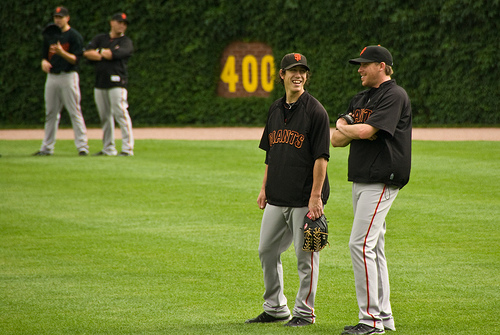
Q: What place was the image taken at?
A: It was taken at the field.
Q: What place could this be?
A: It is a field.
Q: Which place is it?
A: It is a field.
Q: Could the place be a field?
A: Yes, it is a field.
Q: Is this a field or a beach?
A: It is a field.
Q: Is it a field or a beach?
A: It is a field.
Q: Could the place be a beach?
A: No, it is a field.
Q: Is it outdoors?
A: Yes, it is outdoors.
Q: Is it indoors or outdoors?
A: It is outdoors.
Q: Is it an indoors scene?
A: No, it is outdoors.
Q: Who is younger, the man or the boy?
A: The boy is younger than the man.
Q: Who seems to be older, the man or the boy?
A: The man is older than the boy.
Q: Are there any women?
A: No, there are no women.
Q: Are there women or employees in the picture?
A: No, there are no women or employees.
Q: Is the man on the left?
A: Yes, the man is on the left of the image.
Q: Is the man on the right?
A: No, the man is on the left of the image.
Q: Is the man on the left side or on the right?
A: The man is on the left of the image.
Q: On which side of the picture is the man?
A: The man is on the left of the image.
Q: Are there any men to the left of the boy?
A: Yes, there is a man to the left of the boy.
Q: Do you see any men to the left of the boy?
A: Yes, there is a man to the left of the boy.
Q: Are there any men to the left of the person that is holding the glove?
A: Yes, there is a man to the left of the boy.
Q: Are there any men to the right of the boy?
A: No, the man is to the left of the boy.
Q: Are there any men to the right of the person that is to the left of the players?
A: No, the man is to the left of the boy.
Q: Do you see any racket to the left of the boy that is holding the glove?
A: No, there is a man to the left of the boy.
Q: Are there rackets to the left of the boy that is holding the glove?
A: No, there is a man to the left of the boy.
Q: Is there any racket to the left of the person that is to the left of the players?
A: No, there is a man to the left of the boy.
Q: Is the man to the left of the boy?
A: Yes, the man is to the left of the boy.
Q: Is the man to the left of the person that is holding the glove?
A: Yes, the man is to the left of the boy.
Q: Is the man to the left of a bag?
A: No, the man is to the left of the boy.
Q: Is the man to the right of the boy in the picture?
A: No, the man is to the left of the boy.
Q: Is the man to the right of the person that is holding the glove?
A: No, the man is to the left of the boy.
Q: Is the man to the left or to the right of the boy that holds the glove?
A: The man is to the left of the boy.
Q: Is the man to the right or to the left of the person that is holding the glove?
A: The man is to the left of the boy.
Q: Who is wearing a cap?
A: The man is wearing a cap.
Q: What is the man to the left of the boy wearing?
A: The man is wearing a cap.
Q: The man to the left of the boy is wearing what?
A: The man is wearing a cap.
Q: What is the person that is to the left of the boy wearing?
A: The man is wearing a cap.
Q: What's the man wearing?
A: The man is wearing a cap.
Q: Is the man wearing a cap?
A: Yes, the man is wearing a cap.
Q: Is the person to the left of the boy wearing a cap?
A: Yes, the man is wearing a cap.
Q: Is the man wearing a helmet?
A: No, the man is wearing a cap.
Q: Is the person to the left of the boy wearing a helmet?
A: No, the man is wearing a cap.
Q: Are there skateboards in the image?
A: No, there are no skateboards.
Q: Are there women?
A: No, there are no women.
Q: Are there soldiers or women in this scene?
A: No, there are no women or soldiers.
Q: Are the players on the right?
A: Yes, the players are on the right of the image.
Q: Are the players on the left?
A: No, the players are on the right of the image.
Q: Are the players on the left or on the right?
A: The players are on the right of the image.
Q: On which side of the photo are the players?
A: The players are on the right of the image.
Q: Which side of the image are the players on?
A: The players are on the right of the image.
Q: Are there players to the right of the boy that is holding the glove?
A: Yes, there are players to the right of the boy.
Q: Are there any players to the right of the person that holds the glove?
A: Yes, there are players to the right of the boy.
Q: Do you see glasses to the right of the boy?
A: No, there are players to the right of the boy.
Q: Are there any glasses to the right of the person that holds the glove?
A: No, there are players to the right of the boy.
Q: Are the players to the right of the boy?
A: Yes, the players are to the right of the boy.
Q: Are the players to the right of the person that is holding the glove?
A: Yes, the players are to the right of the boy.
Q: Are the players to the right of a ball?
A: No, the players are to the right of the boy.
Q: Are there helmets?
A: No, there are no helmets.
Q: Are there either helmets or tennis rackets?
A: No, there are no helmets or tennis rackets.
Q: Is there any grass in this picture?
A: Yes, there is grass.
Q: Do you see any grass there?
A: Yes, there is grass.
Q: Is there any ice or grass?
A: Yes, there is grass.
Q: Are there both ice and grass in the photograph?
A: No, there is grass but no ice.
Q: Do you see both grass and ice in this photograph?
A: No, there is grass but no ice.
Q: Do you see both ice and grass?
A: No, there is grass but no ice.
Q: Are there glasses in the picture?
A: No, there are no glasses.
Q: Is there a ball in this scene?
A: No, there are no balls.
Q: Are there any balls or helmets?
A: No, there are no balls or helmets.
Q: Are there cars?
A: No, there are no cars.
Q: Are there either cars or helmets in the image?
A: No, there are no cars or helmets.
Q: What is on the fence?
A: The number is on the fence.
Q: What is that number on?
A: The number is on the fence.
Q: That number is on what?
A: The number is on the fence.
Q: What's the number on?
A: The number is on the fence.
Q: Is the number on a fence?
A: Yes, the number is on a fence.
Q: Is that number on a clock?
A: No, the number is on a fence.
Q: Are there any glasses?
A: No, there are no glasses.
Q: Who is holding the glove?
A: The boy is holding the glove.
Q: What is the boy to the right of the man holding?
A: The boy is holding the glove.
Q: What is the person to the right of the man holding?
A: The boy is holding the glove.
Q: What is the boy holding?
A: The boy is holding the glove.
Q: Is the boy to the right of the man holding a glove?
A: Yes, the boy is holding a glove.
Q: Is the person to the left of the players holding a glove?
A: Yes, the boy is holding a glove.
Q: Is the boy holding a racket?
A: No, the boy is holding a glove.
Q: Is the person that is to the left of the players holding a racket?
A: No, the boy is holding a glove.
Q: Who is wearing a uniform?
A: The boy is wearing a uniform.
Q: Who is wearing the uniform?
A: The boy is wearing a uniform.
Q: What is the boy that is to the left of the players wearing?
A: The boy is wearing a uniform.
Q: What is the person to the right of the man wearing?
A: The boy is wearing a uniform.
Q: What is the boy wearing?
A: The boy is wearing a uniform.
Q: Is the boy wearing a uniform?
A: Yes, the boy is wearing a uniform.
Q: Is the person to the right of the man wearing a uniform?
A: Yes, the boy is wearing a uniform.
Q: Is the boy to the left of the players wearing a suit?
A: No, the boy is wearing a uniform.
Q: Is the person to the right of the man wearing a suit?
A: No, the boy is wearing a uniform.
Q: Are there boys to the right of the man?
A: Yes, there is a boy to the right of the man.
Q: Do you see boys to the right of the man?
A: Yes, there is a boy to the right of the man.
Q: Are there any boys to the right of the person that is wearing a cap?
A: Yes, there is a boy to the right of the man.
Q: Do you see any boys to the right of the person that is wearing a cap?
A: Yes, there is a boy to the right of the man.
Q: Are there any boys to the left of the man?
A: No, the boy is to the right of the man.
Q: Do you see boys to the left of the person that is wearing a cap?
A: No, the boy is to the right of the man.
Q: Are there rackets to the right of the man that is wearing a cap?
A: No, there is a boy to the right of the man.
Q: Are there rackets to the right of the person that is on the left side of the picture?
A: No, there is a boy to the right of the man.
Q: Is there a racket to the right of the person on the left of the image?
A: No, there is a boy to the right of the man.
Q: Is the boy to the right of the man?
A: Yes, the boy is to the right of the man.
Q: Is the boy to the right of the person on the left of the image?
A: Yes, the boy is to the right of the man.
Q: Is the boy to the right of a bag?
A: No, the boy is to the right of the man.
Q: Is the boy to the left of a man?
A: No, the boy is to the right of a man.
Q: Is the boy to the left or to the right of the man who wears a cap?
A: The boy is to the right of the man.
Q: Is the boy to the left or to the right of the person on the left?
A: The boy is to the right of the man.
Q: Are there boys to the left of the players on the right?
A: Yes, there is a boy to the left of the players.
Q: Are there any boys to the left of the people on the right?
A: Yes, there is a boy to the left of the players.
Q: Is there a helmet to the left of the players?
A: No, there is a boy to the left of the players.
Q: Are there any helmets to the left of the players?
A: No, there is a boy to the left of the players.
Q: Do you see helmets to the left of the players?
A: No, there is a boy to the left of the players.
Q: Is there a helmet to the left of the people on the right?
A: No, there is a boy to the left of the players.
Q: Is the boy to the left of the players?
A: Yes, the boy is to the left of the players.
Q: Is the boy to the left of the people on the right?
A: Yes, the boy is to the left of the players.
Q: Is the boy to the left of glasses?
A: No, the boy is to the left of the players.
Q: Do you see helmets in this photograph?
A: No, there are no helmets.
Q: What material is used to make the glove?
A: The glove is made of leather.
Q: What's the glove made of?
A: The glove is made of leather.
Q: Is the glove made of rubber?
A: No, the glove is made of leather.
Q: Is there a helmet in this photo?
A: No, there are no helmets.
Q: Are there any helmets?
A: No, there are no helmets.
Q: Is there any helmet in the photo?
A: No, there are no helmets.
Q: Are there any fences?
A: Yes, there is a fence.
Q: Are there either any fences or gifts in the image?
A: Yes, there is a fence.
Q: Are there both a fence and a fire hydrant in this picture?
A: No, there is a fence but no fire hydrants.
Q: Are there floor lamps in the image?
A: No, there are no floor lamps.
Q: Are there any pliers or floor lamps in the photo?
A: No, there are no floor lamps or pliers.